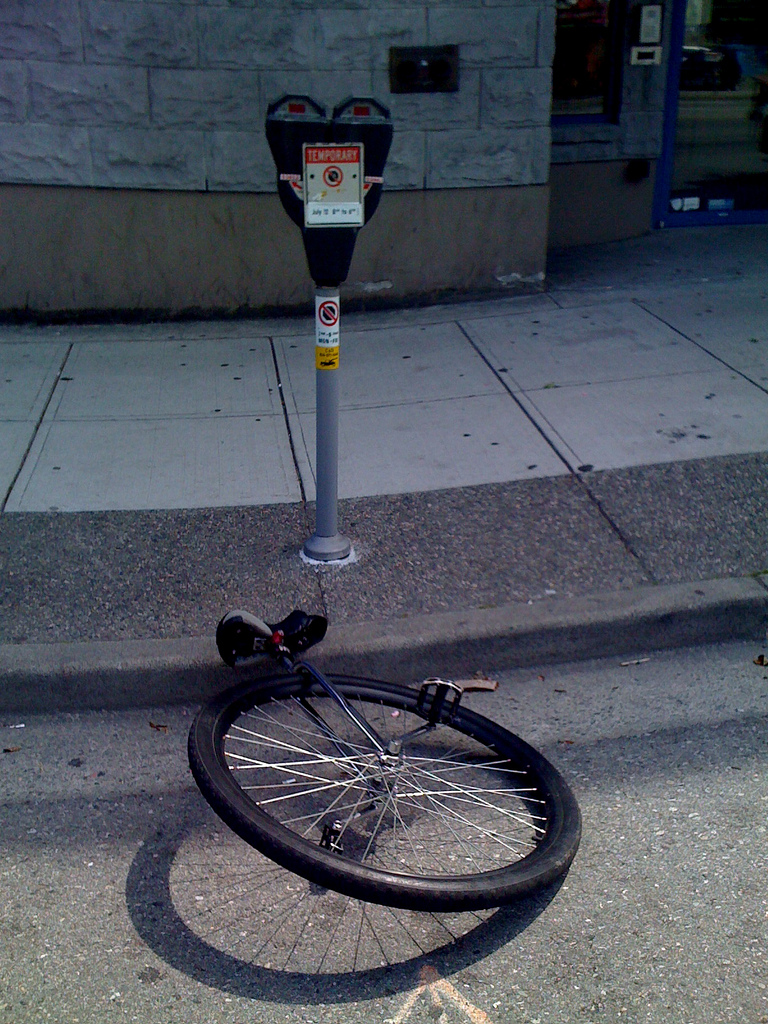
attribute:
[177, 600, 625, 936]
unicycle — black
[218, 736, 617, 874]
wheel — black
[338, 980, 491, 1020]
marking — pink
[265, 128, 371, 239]
meter — black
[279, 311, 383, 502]
pole — silver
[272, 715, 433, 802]
spokes — silver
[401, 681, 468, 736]
pedal — black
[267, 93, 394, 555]
meter — black, gray, for parking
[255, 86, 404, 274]
parking meter — black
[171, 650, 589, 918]
tire — black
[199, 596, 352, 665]
seat — dark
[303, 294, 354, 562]
pole — silver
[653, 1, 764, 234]
frame — blue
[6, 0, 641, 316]
building — stone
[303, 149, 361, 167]
wording — white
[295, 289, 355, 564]
pole — gray, Silver 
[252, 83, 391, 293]
meter — parking 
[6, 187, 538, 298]
brick —  light brown 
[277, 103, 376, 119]
numbers — red , bunch 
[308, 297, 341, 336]
sign — red and white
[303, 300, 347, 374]
sign — white , yellow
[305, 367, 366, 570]
pole — grey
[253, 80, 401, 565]
meter — parking 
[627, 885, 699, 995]
top — black 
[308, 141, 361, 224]
sign — out of order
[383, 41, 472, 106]
plate — black 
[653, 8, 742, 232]
door — blue glass 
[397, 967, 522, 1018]
arrow — orange 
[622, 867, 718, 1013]
top — black 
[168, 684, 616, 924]
cycle — one wheel bike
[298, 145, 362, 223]
sign — red and white 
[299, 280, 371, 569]
post — meter's 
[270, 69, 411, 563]
meter — parking 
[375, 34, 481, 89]
box — black 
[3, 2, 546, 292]
wall — brick 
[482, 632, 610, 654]
edge — darker 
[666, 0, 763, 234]
door frame — blue